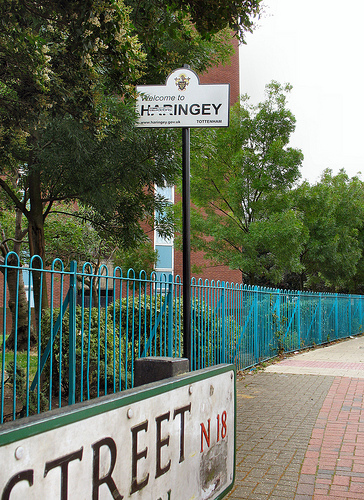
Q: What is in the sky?
A: Clouds.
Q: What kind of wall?
A: Brick.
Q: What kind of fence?
A: Metal.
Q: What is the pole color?
A: Black.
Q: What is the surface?
A: Bricks.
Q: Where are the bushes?
A: Behind the fence.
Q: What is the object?
A: Fence.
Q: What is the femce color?
A: Blue.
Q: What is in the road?
A: Tree.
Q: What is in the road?
A: Fence.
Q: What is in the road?
A: Gate.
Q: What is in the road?
A: Leaves.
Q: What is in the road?
A: Board.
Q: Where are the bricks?
A: Ground.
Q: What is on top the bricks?
A: Sign.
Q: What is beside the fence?
A: Trees.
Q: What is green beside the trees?
A: Bushes.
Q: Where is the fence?
A: Beside the bricks.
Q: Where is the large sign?
A: Top of brick.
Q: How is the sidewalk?
A: Brick made.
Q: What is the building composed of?
A: Bricks.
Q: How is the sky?
A: Cloudy.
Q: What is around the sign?
A: Tall trees.